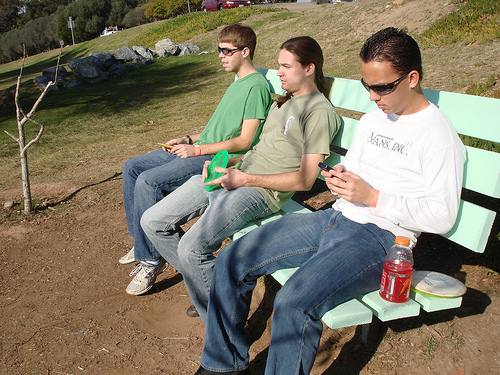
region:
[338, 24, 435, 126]
the head of a man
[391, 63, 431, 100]
the ear of a man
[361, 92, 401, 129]
the mouth of a man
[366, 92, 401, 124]
the chin of a man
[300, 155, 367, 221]
the hands of a man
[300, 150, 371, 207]
the fingers of a man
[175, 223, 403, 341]
the legs of a man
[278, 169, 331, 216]
the elbow of a man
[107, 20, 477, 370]
Three men sitting on a park bench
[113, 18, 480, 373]
Three men sitting on a park bench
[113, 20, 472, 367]
Three men sitting on a park bench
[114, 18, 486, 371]
Three men sitting on a park bench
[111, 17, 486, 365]
Three men sitting on a park bench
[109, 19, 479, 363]
Three men sitting on a park bench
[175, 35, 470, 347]
three men seated on a bench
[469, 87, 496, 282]
bench is green in color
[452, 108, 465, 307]
the bench is made of wood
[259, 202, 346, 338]
the pants are faded blue in color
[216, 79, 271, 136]
the shirt ois green in color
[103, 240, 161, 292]
shoes are white in color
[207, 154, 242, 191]
the plate is green in color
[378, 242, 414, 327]
the bottle has maroon drink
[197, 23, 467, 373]
a man is sitting on a bench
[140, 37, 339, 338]
a man is sitting on a bench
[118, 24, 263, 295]
a man is sitting on a bench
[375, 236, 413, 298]
a bottle of red gatorade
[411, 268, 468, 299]
frisbee is sitting on a bench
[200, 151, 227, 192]
a bright green frisbee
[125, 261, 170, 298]
a man's white tennis shoe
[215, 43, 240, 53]
sunglasses on a man's face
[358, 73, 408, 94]
sunglasses on a man's face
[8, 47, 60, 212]
a small leafless tree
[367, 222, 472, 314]
gatoraid sitting next to frisbe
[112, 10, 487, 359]
3 men resting on a park bench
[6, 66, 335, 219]
men on bench next to tree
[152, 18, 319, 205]
two men holding frisbee's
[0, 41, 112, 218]
tree with rocks behind it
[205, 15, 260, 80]
teenager wearing sunglasses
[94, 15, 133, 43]
white work truck driving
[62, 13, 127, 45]
white work truck next to sign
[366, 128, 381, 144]
black letter on shirt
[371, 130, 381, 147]
black letter on shirt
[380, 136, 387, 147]
black letter on shirt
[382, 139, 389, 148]
black letter on shirt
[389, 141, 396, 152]
black letter on shirt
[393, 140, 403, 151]
black letter on shirt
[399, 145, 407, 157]
black letter on shirt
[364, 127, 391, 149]
black letters on shirt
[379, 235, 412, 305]
plastic bottle on the bench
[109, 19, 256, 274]
man wearing green shirt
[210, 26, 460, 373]
man wearing long sleeve white shirt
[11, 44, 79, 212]
short bare tree near the men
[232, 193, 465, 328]
seat of the bench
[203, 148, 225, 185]
green frisbee the man is holding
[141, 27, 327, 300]
man holding green frisbee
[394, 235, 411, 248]
orange cap on the plastic bottle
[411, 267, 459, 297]
white frisbee on the bench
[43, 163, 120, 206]
shadow of the tree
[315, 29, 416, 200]
guy is looking at his cellphone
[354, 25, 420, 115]
guy is wearing sunglasses